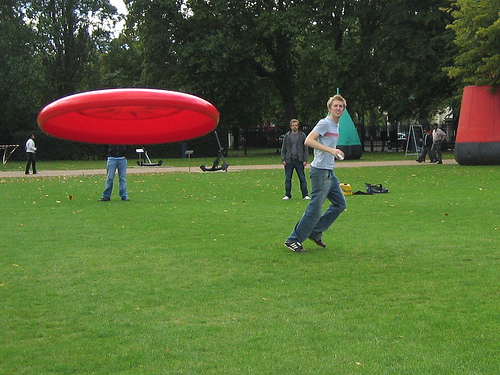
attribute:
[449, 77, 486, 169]
pole — large, red, black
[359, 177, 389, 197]
backpack — lying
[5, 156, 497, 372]
grass — mowed, green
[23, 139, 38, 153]
shirt — white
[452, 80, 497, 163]
structure — large, red, black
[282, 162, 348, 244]
pants — blue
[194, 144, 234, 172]
anchor decor — black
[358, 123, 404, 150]
gate — black, iron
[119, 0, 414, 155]
trees — grouped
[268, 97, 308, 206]
man — standing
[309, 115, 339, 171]
shirt — short sleeve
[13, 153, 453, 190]
sidewalk — long, concrete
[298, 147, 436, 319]
jeans — blue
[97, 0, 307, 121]
tree — green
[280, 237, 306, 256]
shoe — black, white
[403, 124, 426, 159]
swing set — small, white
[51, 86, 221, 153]
frisbee — red, giant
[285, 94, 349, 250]
boy — running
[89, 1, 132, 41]
light — coming through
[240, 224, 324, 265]
shoe — tennis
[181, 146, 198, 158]
metal plaque — small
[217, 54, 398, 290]
people — walking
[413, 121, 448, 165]
people — walking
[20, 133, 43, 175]
person — walking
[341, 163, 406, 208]
backpack — blue